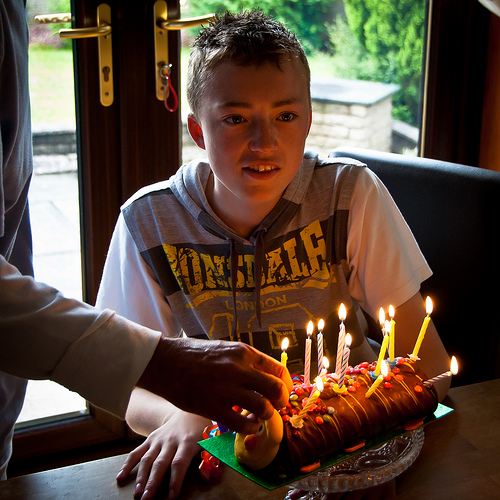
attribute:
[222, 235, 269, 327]
strings — brown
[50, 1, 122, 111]
lock — door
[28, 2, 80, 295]
window — large, glass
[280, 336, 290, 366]
candle — lighted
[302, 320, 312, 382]
candle — lighted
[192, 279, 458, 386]
candle — lighted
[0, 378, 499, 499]
tabletop — woodgrain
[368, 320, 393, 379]
candle — lighted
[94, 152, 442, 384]
tshirt — printed on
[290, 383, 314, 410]
candle — yellow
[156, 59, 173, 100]
latch — door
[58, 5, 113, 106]
handle — door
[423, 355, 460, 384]
candle — lighted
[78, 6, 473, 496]
boy — celebrating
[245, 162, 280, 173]
teeth — white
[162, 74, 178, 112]
loop — red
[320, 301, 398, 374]
candle — lighted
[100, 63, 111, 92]
latch — door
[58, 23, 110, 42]
handle — brass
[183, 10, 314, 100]
hair — spiky , Short 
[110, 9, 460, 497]
boy — young 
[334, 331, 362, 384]
candle — lighted 